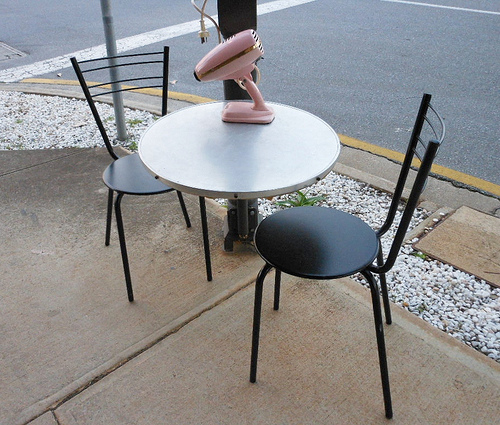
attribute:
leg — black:
[109, 190, 136, 310]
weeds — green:
[278, 187, 328, 208]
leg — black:
[369, 282, 396, 422]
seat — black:
[102, 150, 162, 197]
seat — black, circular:
[250, 204, 381, 282]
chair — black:
[245, 91, 455, 423]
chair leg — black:
[253, 280, 262, 383]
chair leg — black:
[372, 282, 385, 394]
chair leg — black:
[197, 203, 219, 283]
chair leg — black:
[115, 202, 133, 307]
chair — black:
[68, 44, 193, 249]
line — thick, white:
[0, 0, 292, 110]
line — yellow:
[438, 143, 490, 214]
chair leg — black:
[242, 250, 302, 390]